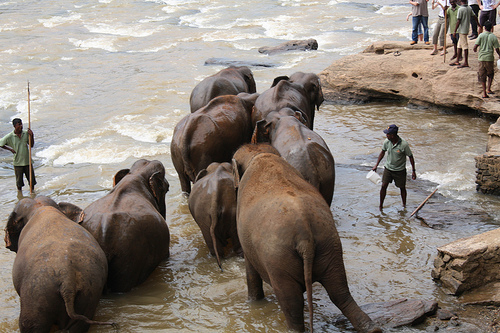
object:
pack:
[169, 65, 382, 333]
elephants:
[76, 159, 170, 300]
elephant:
[1, 196, 108, 332]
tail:
[59, 281, 120, 331]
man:
[372, 124, 416, 211]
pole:
[28, 82, 32, 195]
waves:
[0, 29, 295, 58]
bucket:
[366, 170, 382, 185]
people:
[409, 0, 431, 45]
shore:
[314, 52, 404, 106]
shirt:
[381, 137, 413, 171]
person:
[0, 118, 34, 193]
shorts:
[381, 168, 407, 187]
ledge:
[433, 89, 499, 116]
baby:
[189, 161, 244, 273]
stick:
[408, 188, 439, 219]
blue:
[383, 124, 398, 134]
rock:
[363, 41, 433, 55]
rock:
[258, 38, 318, 55]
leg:
[316, 271, 377, 327]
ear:
[315, 78, 325, 111]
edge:
[474, 156, 496, 196]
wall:
[455, 247, 500, 296]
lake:
[0, 0, 500, 223]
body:
[170, 95, 252, 182]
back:
[255, 152, 313, 215]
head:
[12, 118, 23, 131]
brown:
[0, 39, 65, 64]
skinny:
[210, 213, 224, 273]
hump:
[273, 79, 292, 103]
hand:
[411, 172, 416, 180]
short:
[405, 145, 413, 156]